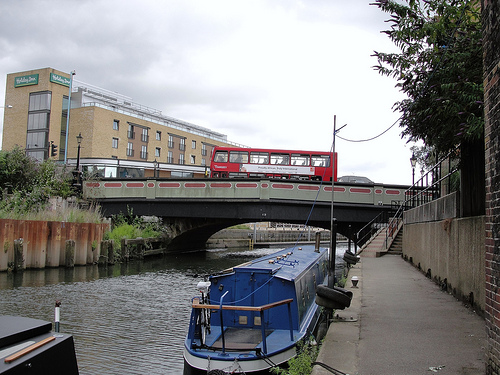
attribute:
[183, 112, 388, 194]
bus — double decker, red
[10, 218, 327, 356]
river — small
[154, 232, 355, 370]
boat — blue, ferry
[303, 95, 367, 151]
light — street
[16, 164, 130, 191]
bush — overgrown, grassy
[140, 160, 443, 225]
bridge — painted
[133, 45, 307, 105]
sky — gray, cloudy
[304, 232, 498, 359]
street — concrete, cement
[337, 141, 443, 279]
staircase — leading, concrete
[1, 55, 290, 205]
inn — holiday, tan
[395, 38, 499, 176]
tree — green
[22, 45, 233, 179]
building — tan, large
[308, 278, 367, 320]
tires — old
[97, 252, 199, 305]
water — ripply